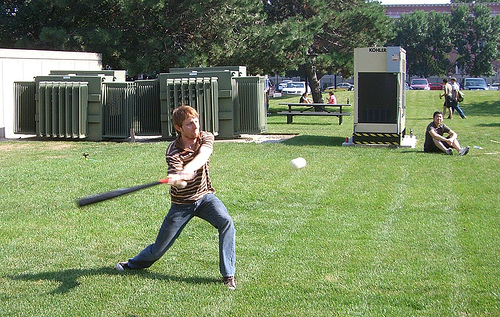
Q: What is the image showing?
A: It is showing a park.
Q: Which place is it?
A: It is a park.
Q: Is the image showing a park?
A: Yes, it is showing a park.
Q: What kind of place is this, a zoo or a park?
A: It is a park.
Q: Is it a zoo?
A: No, it is a park.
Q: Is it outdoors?
A: Yes, it is outdoors.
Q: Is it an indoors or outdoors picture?
A: It is outdoors.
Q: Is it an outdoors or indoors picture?
A: It is outdoors.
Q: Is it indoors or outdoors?
A: It is outdoors.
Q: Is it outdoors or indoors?
A: It is outdoors.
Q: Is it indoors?
A: No, it is outdoors.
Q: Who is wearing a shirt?
A: The man is wearing a shirt.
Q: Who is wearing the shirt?
A: The man is wearing a shirt.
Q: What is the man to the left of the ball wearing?
A: The man is wearing a shirt.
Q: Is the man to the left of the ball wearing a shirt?
A: Yes, the man is wearing a shirt.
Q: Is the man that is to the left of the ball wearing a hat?
A: No, the man is wearing a shirt.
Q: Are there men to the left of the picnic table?
A: Yes, there is a man to the left of the picnic table.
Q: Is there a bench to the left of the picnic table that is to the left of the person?
A: No, there is a man to the left of the picnic table.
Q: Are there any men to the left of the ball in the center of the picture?
A: Yes, there is a man to the left of the ball.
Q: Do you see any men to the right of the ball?
A: No, the man is to the left of the ball.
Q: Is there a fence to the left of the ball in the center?
A: No, there is a man to the left of the ball.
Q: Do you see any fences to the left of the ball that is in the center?
A: No, there is a man to the left of the ball.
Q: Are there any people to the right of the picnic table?
A: Yes, there is a person to the right of the picnic table.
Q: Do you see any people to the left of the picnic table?
A: No, the person is to the right of the picnic table.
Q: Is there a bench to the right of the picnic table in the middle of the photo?
A: No, there is a person to the right of the picnic table.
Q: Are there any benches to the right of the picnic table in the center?
A: No, there is a person to the right of the picnic table.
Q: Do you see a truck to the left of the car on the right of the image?
A: No, there is a person to the left of the car.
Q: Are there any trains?
A: No, there are no trains.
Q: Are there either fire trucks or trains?
A: No, there are no trains or fire trucks.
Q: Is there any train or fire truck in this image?
A: No, there are no trains or fire trucks.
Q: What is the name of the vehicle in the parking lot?
A: The vehicle is a car.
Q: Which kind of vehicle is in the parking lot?
A: The vehicle is a car.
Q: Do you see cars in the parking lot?
A: Yes, there is a car in the parking lot.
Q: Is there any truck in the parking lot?
A: No, there is a car in the parking lot.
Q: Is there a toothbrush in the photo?
A: No, there are no toothbrushes.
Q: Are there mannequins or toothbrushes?
A: No, there are no toothbrushes or mannequins.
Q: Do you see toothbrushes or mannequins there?
A: No, there are no toothbrushes or mannequins.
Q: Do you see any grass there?
A: Yes, there is grass.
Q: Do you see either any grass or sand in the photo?
A: Yes, there is grass.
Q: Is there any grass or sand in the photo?
A: Yes, there is grass.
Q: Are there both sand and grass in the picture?
A: No, there is grass but no sand.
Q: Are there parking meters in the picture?
A: No, there are no parking meters.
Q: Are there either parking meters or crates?
A: No, there are no parking meters or crates.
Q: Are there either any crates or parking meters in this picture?
A: No, there are no parking meters or crates.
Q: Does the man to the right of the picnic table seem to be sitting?
A: Yes, the man is sitting.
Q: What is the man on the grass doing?
A: The man is sitting.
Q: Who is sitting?
A: The man is sitting.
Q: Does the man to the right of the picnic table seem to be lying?
A: No, the man is sitting.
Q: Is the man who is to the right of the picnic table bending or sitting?
A: The man is sitting.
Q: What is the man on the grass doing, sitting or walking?
A: The man is sitting.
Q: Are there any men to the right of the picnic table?
A: Yes, there is a man to the right of the picnic table.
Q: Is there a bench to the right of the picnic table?
A: No, there is a man to the right of the picnic table.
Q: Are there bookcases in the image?
A: No, there are no bookcases.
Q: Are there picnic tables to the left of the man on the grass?
A: Yes, there is a picnic table to the left of the man.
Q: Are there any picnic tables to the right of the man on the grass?
A: No, the picnic table is to the left of the man.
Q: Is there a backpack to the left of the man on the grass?
A: No, there is a picnic table to the left of the man.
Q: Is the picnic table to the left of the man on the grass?
A: Yes, the picnic table is to the left of the man.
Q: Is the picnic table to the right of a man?
A: No, the picnic table is to the left of a man.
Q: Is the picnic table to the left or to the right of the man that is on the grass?
A: The picnic table is to the left of the man.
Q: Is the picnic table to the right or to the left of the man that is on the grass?
A: The picnic table is to the left of the man.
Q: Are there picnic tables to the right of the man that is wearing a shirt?
A: Yes, there is a picnic table to the right of the man.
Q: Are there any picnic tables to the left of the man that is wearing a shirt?
A: No, the picnic table is to the right of the man.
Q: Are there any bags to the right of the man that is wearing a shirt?
A: No, there is a picnic table to the right of the man.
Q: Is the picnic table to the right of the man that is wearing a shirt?
A: Yes, the picnic table is to the right of the man.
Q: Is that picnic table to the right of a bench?
A: No, the picnic table is to the right of the man.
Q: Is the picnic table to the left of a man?
A: No, the picnic table is to the right of a man.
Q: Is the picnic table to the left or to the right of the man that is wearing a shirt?
A: The picnic table is to the right of the man.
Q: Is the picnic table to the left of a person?
A: Yes, the picnic table is to the left of a person.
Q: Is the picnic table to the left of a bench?
A: No, the picnic table is to the left of a person.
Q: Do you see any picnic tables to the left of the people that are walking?
A: Yes, there is a picnic table to the left of the people.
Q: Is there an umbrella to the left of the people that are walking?
A: No, there is a picnic table to the left of the people.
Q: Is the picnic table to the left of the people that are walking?
A: Yes, the picnic table is to the left of the people.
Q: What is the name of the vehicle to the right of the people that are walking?
A: The vehicle is a car.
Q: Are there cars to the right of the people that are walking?
A: Yes, there is a car to the right of the people.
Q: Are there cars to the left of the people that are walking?
A: No, the car is to the right of the people.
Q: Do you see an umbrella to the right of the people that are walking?
A: No, there is a car to the right of the people.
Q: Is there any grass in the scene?
A: Yes, there is grass.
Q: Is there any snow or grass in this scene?
A: Yes, there is grass.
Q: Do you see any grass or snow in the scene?
A: Yes, there is grass.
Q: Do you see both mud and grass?
A: No, there is grass but no mud.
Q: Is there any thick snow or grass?
A: Yes, there is thick grass.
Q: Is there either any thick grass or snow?
A: Yes, there is thick grass.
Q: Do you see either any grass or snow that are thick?
A: Yes, the grass is thick.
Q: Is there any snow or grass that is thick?
A: Yes, the grass is thick.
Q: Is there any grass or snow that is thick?
A: Yes, the grass is thick.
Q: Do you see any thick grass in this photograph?
A: Yes, there is thick grass.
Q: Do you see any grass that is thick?
A: Yes, there is grass that is thick.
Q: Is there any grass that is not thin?
A: Yes, there is thick grass.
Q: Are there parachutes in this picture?
A: No, there are no parachutes.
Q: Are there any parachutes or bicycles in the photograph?
A: No, there are no parachutes or bicycles.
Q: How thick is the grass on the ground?
A: The grass is thick.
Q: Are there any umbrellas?
A: No, there are no umbrellas.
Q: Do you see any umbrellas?
A: No, there are no umbrellas.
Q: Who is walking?
A: The people are walking.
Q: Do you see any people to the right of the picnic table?
A: Yes, there are people to the right of the picnic table.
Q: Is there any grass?
A: Yes, there is grass.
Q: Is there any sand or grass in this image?
A: Yes, there is grass.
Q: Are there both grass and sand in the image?
A: No, there is grass but no sand.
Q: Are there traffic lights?
A: No, there are no traffic lights.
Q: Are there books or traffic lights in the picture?
A: No, there are no traffic lights or books.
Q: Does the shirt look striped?
A: Yes, the shirt is striped.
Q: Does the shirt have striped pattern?
A: Yes, the shirt is striped.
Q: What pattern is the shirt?
A: The shirt is striped.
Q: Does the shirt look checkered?
A: No, the shirt is striped.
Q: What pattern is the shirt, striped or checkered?
A: The shirt is striped.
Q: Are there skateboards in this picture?
A: No, there are no skateboards.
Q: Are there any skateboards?
A: No, there are no skateboards.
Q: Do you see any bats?
A: Yes, there is a bat.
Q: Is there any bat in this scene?
A: Yes, there is a bat.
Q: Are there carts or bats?
A: Yes, there is a bat.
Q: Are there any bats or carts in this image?
A: Yes, there is a bat.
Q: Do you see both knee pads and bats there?
A: No, there is a bat but no knee pads.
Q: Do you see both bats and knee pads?
A: No, there is a bat but no knee pads.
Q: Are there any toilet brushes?
A: No, there are no toilet brushes.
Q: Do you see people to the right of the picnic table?
A: Yes, there is a person to the right of the picnic table.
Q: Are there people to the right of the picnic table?
A: Yes, there is a person to the right of the picnic table.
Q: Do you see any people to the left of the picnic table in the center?
A: No, the person is to the right of the picnic table.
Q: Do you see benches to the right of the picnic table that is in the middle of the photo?
A: No, there is a person to the right of the picnic table.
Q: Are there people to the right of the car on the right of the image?
A: No, the person is to the left of the car.